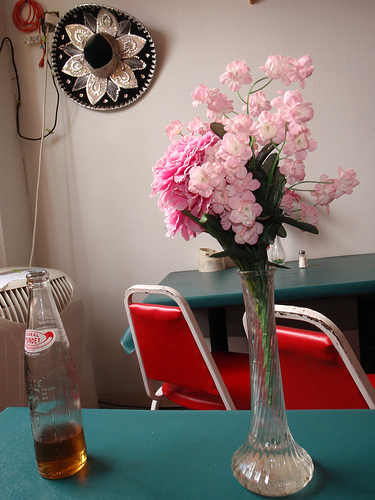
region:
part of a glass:
[261, 395, 289, 431]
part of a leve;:
[57, 412, 81, 457]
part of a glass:
[264, 418, 303, 456]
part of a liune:
[259, 388, 283, 428]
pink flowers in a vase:
[162, 60, 348, 484]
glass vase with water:
[234, 264, 314, 492]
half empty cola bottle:
[17, 267, 97, 476]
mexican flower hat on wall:
[52, 6, 154, 113]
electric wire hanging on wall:
[5, 3, 56, 145]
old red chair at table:
[123, 274, 218, 423]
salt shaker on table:
[296, 247, 315, 270]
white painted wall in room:
[70, 164, 132, 263]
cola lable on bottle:
[18, 327, 59, 357]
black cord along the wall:
[100, 385, 142, 415]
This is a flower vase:
[157, 52, 349, 484]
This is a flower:
[264, 40, 297, 91]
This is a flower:
[283, 48, 329, 100]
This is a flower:
[319, 151, 366, 220]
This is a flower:
[252, 170, 317, 263]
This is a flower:
[163, 191, 208, 262]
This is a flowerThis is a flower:
[167, 115, 223, 210]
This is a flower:
[202, 140, 264, 232]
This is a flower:
[166, 147, 214, 216]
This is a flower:
[218, 125, 258, 202]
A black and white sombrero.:
[48, 1, 160, 113]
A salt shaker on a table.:
[295, 247, 309, 270]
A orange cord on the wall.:
[8, 0, 50, 69]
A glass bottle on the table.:
[21, 264, 89, 482]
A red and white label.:
[25, 327, 55, 354]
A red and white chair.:
[120, 282, 253, 413]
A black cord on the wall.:
[1, 7, 61, 142]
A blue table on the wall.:
[114, 248, 374, 407]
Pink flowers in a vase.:
[149, 53, 352, 497]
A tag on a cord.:
[22, 33, 46, 47]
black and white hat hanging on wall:
[51, 2, 157, 109]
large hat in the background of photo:
[52, 0, 155, 110]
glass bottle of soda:
[20, 267, 89, 478]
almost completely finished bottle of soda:
[19, 270, 88, 478]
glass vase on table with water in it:
[229, 267, 313, 497]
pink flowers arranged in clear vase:
[154, 53, 360, 272]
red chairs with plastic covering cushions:
[121, 284, 373, 408]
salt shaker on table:
[297, 248, 306, 267]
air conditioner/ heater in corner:
[0, 263, 99, 410]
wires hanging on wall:
[0, 1, 61, 266]